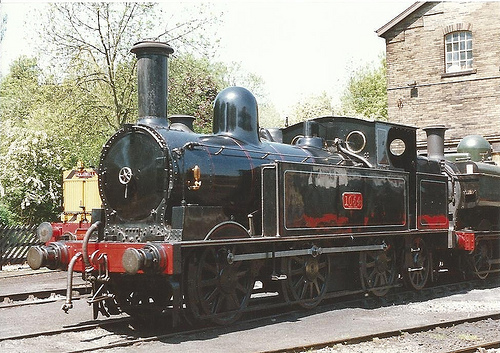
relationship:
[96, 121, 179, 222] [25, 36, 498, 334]
front is round on train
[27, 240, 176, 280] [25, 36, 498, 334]
bumper is red on train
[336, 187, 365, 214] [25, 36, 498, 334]
plate is red on train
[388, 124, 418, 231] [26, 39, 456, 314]
door to engine car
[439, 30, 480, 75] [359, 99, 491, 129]
building has window in building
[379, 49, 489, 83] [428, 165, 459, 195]
building made of brown shades of bricks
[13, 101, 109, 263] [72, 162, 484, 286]
trees on side of train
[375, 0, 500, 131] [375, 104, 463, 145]
building brown and made of bricks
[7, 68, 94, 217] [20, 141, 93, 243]
trees are green and leafy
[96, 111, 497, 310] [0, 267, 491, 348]
train on tracks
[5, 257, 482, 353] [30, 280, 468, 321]
choo choo train tracks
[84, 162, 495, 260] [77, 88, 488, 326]
black choo choo train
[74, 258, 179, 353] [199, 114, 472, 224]
redpaint on black train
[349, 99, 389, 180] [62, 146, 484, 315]
one tree in back of a train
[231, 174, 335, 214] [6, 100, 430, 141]
blue sky on sunny day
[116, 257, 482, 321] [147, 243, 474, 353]
four wheels in a row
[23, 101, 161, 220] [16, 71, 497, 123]
bushes in background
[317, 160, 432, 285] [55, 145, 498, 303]
number on side of train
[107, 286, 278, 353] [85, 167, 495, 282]
wheel on front of train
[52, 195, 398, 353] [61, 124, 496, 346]
stack on top of train